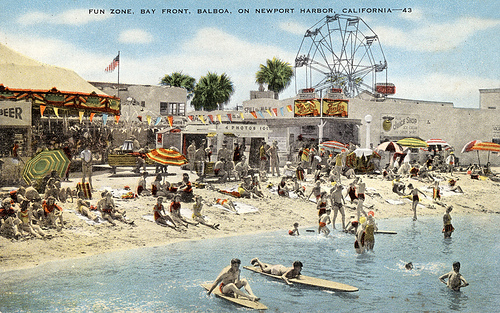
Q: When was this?
A: Daytime.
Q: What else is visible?
A: Water.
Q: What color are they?
A: White.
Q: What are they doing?
A: Sun bathing.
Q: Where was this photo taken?
A: At a beach.